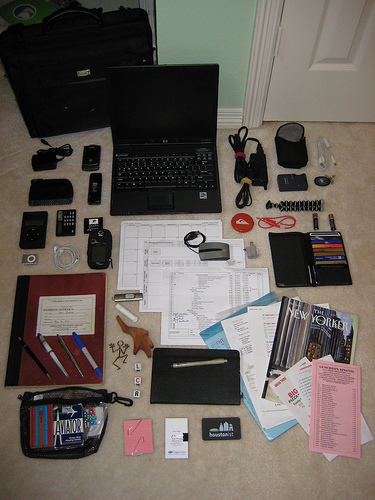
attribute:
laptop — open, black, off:
[97, 53, 233, 220]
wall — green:
[158, 4, 257, 65]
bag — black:
[0, 5, 161, 141]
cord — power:
[224, 122, 260, 214]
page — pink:
[306, 356, 368, 462]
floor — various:
[6, 119, 374, 499]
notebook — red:
[3, 265, 112, 390]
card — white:
[160, 413, 193, 463]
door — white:
[260, 4, 374, 129]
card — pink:
[115, 414, 158, 465]